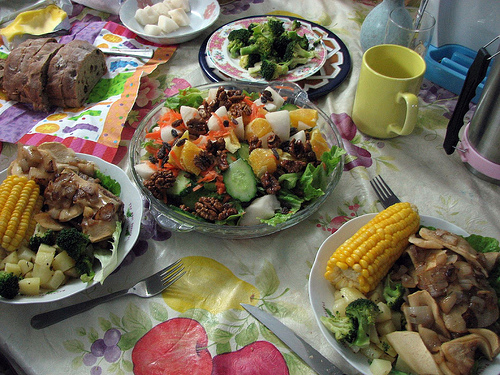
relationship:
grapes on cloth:
[77, 323, 124, 373] [4, 4, 499, 374]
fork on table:
[34, 254, 221, 341] [59, 41, 461, 338]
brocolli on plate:
[275, 134, 307, 166] [126, 74, 349, 248]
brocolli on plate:
[244, 17, 284, 57] [192, 6, 361, 104]